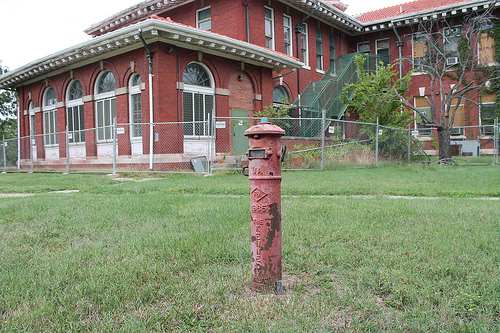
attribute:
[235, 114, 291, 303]
fire hydrant — rusty, old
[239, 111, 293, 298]
fire hydrant — red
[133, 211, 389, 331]
grass — green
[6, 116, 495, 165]
fence — metal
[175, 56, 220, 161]
door — white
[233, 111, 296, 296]
water hydrant — old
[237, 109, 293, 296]
water hydrant — old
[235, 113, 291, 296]
bollard — red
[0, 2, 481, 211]
building — Large abandoned brick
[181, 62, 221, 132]
windows — Large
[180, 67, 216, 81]
tops — arched 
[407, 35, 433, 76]
windows — broken 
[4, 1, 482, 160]
building — brick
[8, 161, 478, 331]
lawn — Mowed green grass 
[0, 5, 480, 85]
roof — Light red terra cotta 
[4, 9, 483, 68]
roof — White painted decorative effects 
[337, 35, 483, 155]
bushes — Green overgrown tall 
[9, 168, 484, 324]
area — grassy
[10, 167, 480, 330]
grass — green 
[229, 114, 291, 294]
pole — red 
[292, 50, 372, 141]
staircase — green covered 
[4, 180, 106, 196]
sidewalk — gray 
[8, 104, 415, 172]
fence — silver metal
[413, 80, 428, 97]
sign — white 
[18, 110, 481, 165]
fence — silver metal , Long chainlink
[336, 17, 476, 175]
tree — green 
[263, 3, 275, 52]
window — rectangular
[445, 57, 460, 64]
unit — a/c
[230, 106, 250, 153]
door — green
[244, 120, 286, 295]
hydrant — red, tall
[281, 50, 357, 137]
stairs — green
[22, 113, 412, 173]
fence — chain link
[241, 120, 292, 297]
hydrant — red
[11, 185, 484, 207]
path — concrete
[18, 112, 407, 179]
fence — chain link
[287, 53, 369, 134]
stairs — green